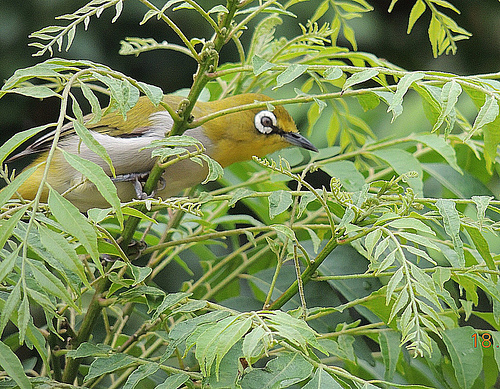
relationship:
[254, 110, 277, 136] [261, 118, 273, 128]
ring around eye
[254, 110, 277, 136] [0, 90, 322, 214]
ring on bird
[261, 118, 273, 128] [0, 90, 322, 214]
eye of bird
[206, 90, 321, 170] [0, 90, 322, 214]
head of bird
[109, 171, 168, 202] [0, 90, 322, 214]
talons of bird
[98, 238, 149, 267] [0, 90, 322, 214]
talons of bird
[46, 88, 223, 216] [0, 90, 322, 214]
body of bird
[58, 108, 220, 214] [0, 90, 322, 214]
underside of bird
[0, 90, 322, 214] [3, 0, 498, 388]
bird on plants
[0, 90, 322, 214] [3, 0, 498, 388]
bird on bush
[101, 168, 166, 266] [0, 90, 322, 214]
feet of bird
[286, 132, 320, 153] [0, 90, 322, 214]
beak of bird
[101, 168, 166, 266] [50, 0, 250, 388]
feet grip plants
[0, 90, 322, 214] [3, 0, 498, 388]
bird in plants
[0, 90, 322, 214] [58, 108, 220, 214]
bird has belly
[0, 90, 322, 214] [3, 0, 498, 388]
bird in bush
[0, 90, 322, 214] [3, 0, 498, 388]
bird in tree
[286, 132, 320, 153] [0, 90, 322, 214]
beak on bird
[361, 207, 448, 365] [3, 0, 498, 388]
leaves on plant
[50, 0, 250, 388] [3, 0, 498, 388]
stem on plants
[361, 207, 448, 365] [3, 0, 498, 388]
leaves on plants